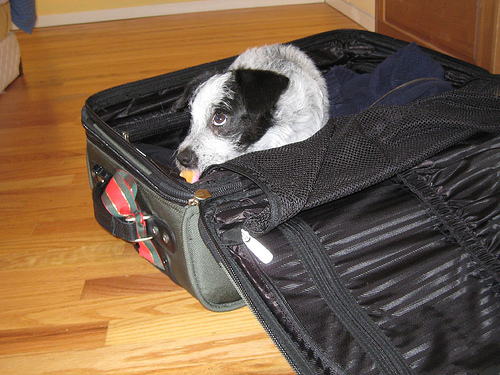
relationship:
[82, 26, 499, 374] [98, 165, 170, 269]
luggage has ribbon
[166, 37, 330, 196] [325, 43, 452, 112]
dog laying on top of clothes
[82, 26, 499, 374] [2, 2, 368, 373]
luggage on floor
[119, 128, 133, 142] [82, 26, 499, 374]
zipper inside luggage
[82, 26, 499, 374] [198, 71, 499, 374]
luggage has cover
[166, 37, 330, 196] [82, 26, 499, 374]
dog peeping out of luggage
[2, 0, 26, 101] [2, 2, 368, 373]
mattress on floor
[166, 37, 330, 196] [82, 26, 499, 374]
dog laying in luggage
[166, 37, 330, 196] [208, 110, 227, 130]
dog has eye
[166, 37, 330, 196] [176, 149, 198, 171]
dog has nose